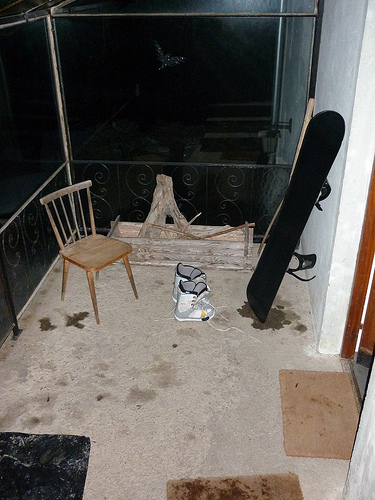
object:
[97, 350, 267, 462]
ground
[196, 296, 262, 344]
laces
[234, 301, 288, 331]
spot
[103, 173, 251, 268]
wood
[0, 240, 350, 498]
floor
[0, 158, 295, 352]
railing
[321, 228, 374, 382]
trim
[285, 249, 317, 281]
bindings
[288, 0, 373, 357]
wall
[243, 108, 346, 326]
snowboard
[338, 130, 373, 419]
door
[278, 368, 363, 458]
mat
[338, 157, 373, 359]
wooden door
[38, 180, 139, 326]
chair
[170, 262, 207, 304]
snow boots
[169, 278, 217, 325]
snowboard boots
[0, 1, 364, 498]
porch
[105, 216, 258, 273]
container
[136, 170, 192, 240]
wood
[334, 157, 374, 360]
door trim